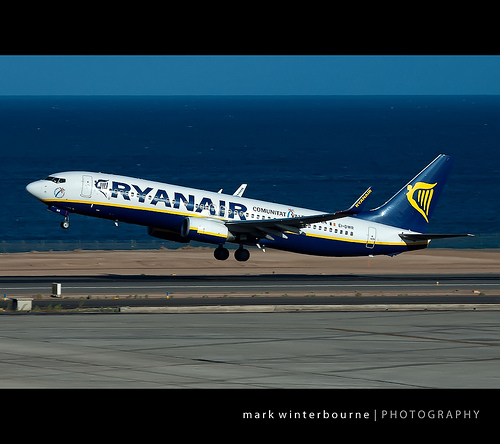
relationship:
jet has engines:
[26, 149, 475, 260] [144, 216, 230, 243]